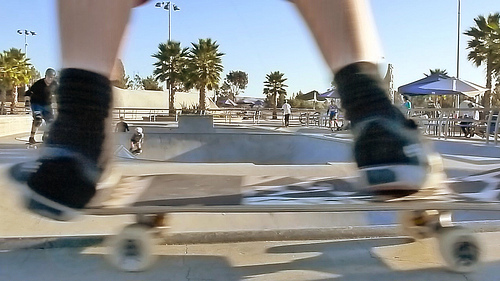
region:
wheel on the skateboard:
[90, 215, 176, 272]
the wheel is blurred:
[422, 225, 487, 264]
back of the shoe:
[350, 136, 417, 190]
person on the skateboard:
[15, 114, 475, 259]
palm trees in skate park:
[151, 39, 234, 148]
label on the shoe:
[352, 156, 399, 188]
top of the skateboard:
[205, 165, 315, 208]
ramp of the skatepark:
[158, 133, 285, 167]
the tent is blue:
[410, 65, 464, 89]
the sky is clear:
[236, 27, 268, 60]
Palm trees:
[0, 11, 499, 115]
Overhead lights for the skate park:
[15, 0, 180, 39]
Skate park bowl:
[107, 130, 357, 167]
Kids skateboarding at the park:
[6, 0, 498, 272]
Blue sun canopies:
[321, 71, 489, 98]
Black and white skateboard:
[7, 155, 498, 272]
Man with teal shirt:
[400, 94, 410, 116]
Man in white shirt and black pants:
[280, 99, 290, 126]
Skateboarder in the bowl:
[129, 127, 143, 157]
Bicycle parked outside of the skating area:
[298, 110, 321, 123]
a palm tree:
[467, 13, 486, 60]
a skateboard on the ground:
[30, 168, 494, 248]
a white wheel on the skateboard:
[106, 225, 162, 257]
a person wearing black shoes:
[35, 5, 437, 194]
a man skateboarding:
[21, 73, 72, 152]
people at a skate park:
[207, 85, 457, 155]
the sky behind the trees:
[213, 21, 305, 83]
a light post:
[158, 0, 180, 7]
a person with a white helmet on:
[126, 126, 149, 155]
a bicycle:
[296, 105, 324, 120]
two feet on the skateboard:
[9, 117, 483, 225]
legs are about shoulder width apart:
[21, 0, 462, 221]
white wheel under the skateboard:
[106, 225, 160, 273]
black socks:
[330, 57, 407, 119]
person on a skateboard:
[20, 68, 75, 145]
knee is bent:
[28, 110, 45, 133]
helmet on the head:
[133, 125, 146, 132]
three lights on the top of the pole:
[13, 28, 43, 38]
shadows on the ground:
[2, 222, 499, 277]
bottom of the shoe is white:
[351, 166, 432, 189]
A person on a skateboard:
[15, 1, 442, 193]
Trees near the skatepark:
[155, 38, 220, 113]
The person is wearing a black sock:
[47, 69, 112, 161]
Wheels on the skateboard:
[106, 225, 486, 270]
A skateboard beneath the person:
[9, 159, 497, 269]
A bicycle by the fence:
[301, 110, 320, 124]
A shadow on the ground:
[1, 235, 498, 279]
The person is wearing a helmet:
[45, 63, 56, 78]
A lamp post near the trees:
[156, 1, 180, 91]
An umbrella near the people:
[396, 75, 488, 132]